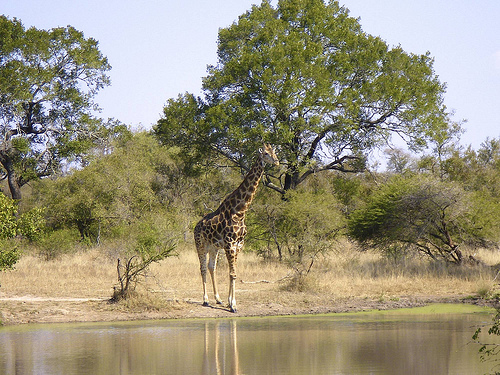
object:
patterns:
[209, 207, 244, 255]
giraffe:
[192, 145, 282, 314]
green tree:
[148, 0, 459, 200]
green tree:
[0, 13, 131, 200]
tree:
[114, 235, 179, 302]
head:
[248, 139, 283, 169]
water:
[0, 302, 497, 374]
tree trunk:
[4, 165, 25, 202]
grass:
[0, 244, 500, 309]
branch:
[403, 217, 442, 240]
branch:
[440, 211, 454, 239]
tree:
[338, 175, 485, 272]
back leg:
[207, 252, 220, 304]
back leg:
[196, 250, 210, 305]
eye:
[264, 151, 268, 155]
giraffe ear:
[252, 145, 266, 154]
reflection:
[202, 318, 247, 373]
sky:
[119, 23, 216, 113]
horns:
[252, 139, 282, 153]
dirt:
[158, 295, 203, 322]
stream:
[3, 297, 494, 368]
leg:
[224, 240, 236, 310]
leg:
[225, 244, 243, 306]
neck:
[219, 157, 266, 215]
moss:
[3, 299, 497, 329]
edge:
[0, 283, 500, 323]